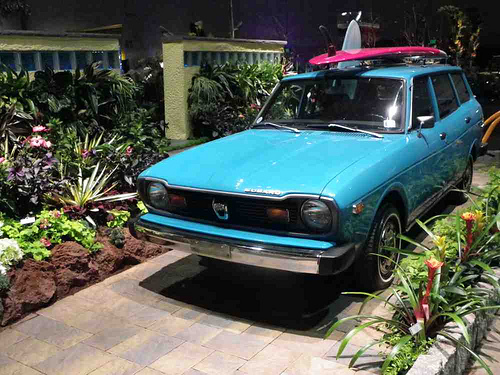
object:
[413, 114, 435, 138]
mirror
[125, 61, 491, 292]
car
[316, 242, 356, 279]
black cap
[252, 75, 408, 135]
windshield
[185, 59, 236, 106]
tennis racket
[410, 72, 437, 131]
window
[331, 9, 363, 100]
surfboard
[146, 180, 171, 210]
headlight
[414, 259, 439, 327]
redplant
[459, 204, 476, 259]
redplant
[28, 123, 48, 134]
redplant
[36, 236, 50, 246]
redplant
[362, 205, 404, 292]
wheel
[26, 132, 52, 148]
flowers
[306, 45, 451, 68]
surfboard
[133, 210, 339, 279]
bumper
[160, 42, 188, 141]
wall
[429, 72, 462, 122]
windows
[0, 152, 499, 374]
ground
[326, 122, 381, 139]
wiper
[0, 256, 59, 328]
rocks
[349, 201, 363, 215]
side marker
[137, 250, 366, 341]
shadow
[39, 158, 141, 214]
plant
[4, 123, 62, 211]
plant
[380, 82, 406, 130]
light glare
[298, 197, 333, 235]
headlight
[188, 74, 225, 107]
plants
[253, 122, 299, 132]
wiper